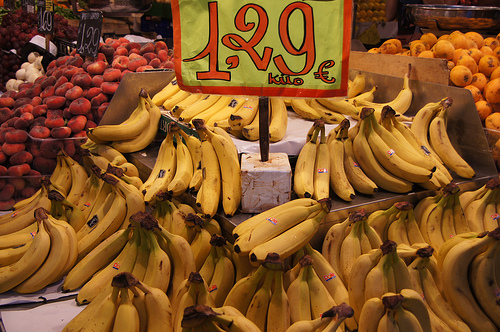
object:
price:
[182, 0, 335, 86]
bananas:
[0, 66, 500, 332]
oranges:
[365, 30, 500, 162]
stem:
[312, 116, 326, 130]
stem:
[138, 88, 148, 98]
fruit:
[0, 0, 499, 332]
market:
[0, 0, 500, 331]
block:
[238, 151, 292, 215]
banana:
[60, 225, 129, 294]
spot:
[158, 260, 163, 272]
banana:
[230, 196, 324, 237]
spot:
[235, 238, 240, 242]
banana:
[419, 192, 449, 261]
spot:
[434, 215, 438, 223]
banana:
[429, 109, 477, 180]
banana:
[305, 97, 348, 124]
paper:
[159, 105, 416, 157]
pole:
[257, 96, 272, 162]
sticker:
[317, 167, 329, 173]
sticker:
[323, 272, 337, 282]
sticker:
[157, 169, 167, 179]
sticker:
[420, 145, 431, 156]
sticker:
[86, 214, 100, 229]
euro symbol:
[313, 59, 337, 85]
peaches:
[30, 75, 92, 133]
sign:
[78, 9, 104, 59]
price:
[76, 11, 100, 57]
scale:
[401, 2, 500, 49]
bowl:
[410, 4, 499, 37]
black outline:
[182, 0, 337, 86]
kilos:
[267, 72, 304, 87]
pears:
[5, 51, 46, 93]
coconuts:
[15, 61, 45, 84]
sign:
[36, 9, 56, 35]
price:
[36, 8, 52, 31]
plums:
[0, 46, 24, 93]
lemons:
[355, 1, 386, 24]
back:
[0, 0, 174, 94]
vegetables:
[3, 1, 80, 21]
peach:
[127, 52, 148, 71]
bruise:
[135, 58, 137, 60]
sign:
[356, 22, 381, 46]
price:
[364, 28, 379, 41]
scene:
[0, 0, 500, 331]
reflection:
[412, 7, 495, 30]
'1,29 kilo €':
[180, 0, 336, 86]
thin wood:
[349, 50, 451, 86]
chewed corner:
[439, 58, 452, 71]